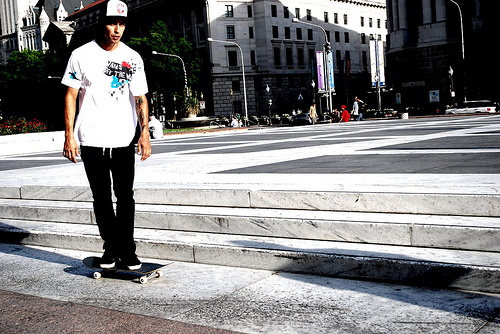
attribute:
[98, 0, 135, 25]
baseball cap — black, white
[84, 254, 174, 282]
skateboard — black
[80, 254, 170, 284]
skateboard — black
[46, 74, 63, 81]
lamp post — gray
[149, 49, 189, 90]
lamp post — gray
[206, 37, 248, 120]
lamp post — gray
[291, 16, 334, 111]
lamp post — gray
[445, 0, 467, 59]
lamp post — gray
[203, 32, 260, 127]
light — tall